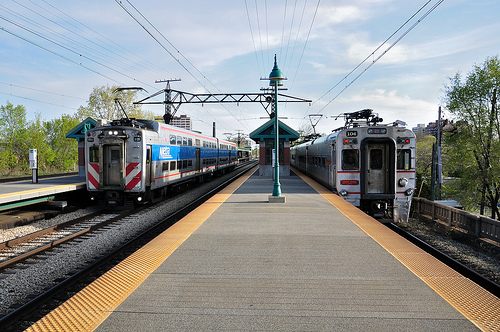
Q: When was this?
A: Daytime.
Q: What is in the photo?
A: Trains.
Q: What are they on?
A: Rail tracks.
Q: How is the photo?
A: Clear.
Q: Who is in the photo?
A: Nobody.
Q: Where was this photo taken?
A: At a metro station.